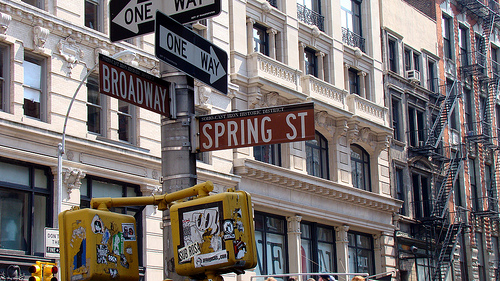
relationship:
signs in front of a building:
[94, 0, 323, 144] [2, 0, 499, 277]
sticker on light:
[180, 214, 222, 259] [167, 190, 257, 274]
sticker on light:
[222, 218, 234, 245] [167, 190, 257, 274]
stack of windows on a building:
[384, 27, 444, 217] [381, 3, 477, 279]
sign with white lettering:
[179, 103, 339, 158] [200, 113, 307, 149]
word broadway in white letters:
[99, 61, 170, 116] [101, 66, 174, 120]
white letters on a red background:
[101, 66, 174, 120] [99, 61, 171, 116]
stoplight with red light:
[15, 222, 72, 279] [46, 263, 61, 274]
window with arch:
[336, 134, 380, 205] [350, 141, 371, 164]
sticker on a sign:
[174, 240, 203, 263] [161, 180, 261, 277]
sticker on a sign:
[190, 242, 231, 268] [161, 180, 261, 277]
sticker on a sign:
[222, 218, 235, 241] [161, 180, 261, 277]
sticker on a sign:
[231, 233, 248, 260] [161, 180, 261, 277]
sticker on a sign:
[175, 215, 192, 242] [161, 180, 261, 277]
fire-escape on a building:
[398, 77, 463, 279] [380, 32, 498, 279]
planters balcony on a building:
[297, 3, 377, 63] [232, 3, 384, 279]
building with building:
[232, 3, 384, 279] [381, 3, 477, 279]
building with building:
[232, 3, 384, 279] [4, 4, 224, 274]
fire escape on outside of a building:
[401, 44, 488, 278] [381, 3, 477, 279]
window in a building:
[351, 143, 371, 187] [246, 3, 396, 279]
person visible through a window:
[3, 215, 17, 249] [1, 161, 53, 256]